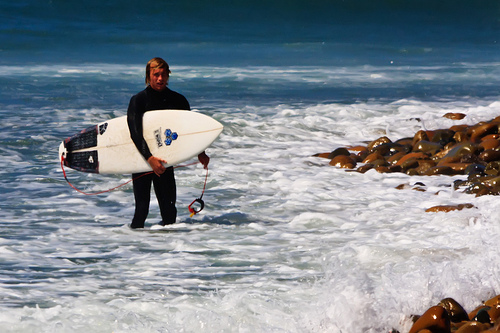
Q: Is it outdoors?
A: Yes, it is outdoors.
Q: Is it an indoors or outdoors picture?
A: It is outdoors.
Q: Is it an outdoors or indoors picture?
A: It is outdoors.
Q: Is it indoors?
A: No, it is outdoors.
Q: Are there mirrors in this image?
A: No, there are no mirrors.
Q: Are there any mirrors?
A: No, there are no mirrors.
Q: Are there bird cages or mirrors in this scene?
A: No, there are no mirrors or bird cages.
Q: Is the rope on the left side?
A: Yes, the rope is on the left of the image.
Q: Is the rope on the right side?
A: No, the rope is on the left of the image.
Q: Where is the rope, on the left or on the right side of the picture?
A: The rope is on the left of the image.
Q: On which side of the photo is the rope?
A: The rope is on the left of the image.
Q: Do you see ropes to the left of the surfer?
A: Yes, there is a rope to the left of the surfer.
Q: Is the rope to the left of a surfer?
A: Yes, the rope is to the left of a surfer.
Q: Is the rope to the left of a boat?
A: No, the rope is to the left of a surfer.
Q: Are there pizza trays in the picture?
A: No, there are no pizza trays.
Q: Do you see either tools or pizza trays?
A: No, there are no pizza trays or tools.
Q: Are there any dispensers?
A: No, there are no dispensers.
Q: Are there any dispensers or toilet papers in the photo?
A: No, there are no dispensers or toilet papers.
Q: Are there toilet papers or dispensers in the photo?
A: No, there are no dispensers or toilet papers.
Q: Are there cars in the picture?
A: No, there are no cars.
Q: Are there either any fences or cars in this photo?
A: No, there are no cars or fences.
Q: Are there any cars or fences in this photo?
A: No, there are no cars or fences.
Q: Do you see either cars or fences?
A: No, there are no cars or fences.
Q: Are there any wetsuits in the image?
A: Yes, there is a wetsuit.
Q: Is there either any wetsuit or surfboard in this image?
A: Yes, there is a wetsuit.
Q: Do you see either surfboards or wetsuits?
A: Yes, there is a wetsuit.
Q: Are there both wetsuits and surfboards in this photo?
A: Yes, there are both a wetsuit and a surfboard.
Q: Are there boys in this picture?
A: No, there are no boys.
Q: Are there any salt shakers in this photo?
A: No, there are no salt shakers.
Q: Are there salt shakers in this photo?
A: No, there are no salt shakers.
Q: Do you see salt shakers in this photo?
A: No, there are no salt shakers.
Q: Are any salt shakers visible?
A: No, there are no salt shakers.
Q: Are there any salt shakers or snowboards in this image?
A: No, there are no salt shakers or snowboards.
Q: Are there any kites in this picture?
A: No, there are no kites.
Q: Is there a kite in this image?
A: No, there are no kites.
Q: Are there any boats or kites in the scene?
A: No, there are no kites or boats.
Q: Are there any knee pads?
A: No, there are no knee pads.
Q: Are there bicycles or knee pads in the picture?
A: No, there are no knee pads or bicycles.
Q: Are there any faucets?
A: No, there are no faucets.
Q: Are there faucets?
A: No, there are no faucets.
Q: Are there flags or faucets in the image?
A: No, there are no faucets or flags.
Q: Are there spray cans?
A: No, there are no spray cans.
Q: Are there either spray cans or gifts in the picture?
A: No, there are no spray cans or gifts.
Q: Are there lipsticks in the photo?
A: No, there are no lipsticks.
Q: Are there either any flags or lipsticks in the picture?
A: No, there are no lipsticks or flags.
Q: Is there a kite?
A: No, there are no kites.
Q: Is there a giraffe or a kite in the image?
A: No, there are no kites or giraffes.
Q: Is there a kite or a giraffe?
A: No, there are no kites or giraffes.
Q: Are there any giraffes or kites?
A: No, there are no kites or giraffes.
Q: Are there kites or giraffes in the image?
A: No, there are no kites or giraffes.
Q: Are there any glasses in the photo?
A: No, there are no glasses.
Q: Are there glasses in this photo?
A: No, there are no glasses.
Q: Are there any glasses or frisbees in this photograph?
A: No, there are no glasses or frisbees.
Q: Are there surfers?
A: Yes, there is a surfer.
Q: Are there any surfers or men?
A: Yes, there is a surfer.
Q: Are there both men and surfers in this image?
A: Yes, there are both a surfer and a man.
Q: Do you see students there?
A: No, there are no students.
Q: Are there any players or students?
A: No, there are no students or players.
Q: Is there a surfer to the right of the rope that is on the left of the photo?
A: Yes, there is a surfer to the right of the rope.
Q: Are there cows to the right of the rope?
A: No, there is a surfer to the right of the rope.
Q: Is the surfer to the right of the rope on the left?
A: Yes, the surfer is to the right of the rope.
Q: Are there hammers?
A: No, there are no hammers.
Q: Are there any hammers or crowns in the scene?
A: No, there are no hammers or crowns.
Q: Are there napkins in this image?
A: No, there are no napkins.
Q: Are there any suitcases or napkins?
A: No, there are no napkins or suitcases.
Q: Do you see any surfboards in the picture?
A: Yes, there is a surfboard.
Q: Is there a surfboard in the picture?
A: Yes, there is a surfboard.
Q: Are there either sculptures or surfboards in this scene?
A: Yes, there is a surfboard.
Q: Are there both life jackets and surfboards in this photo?
A: No, there is a surfboard but no life jackets.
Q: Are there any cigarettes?
A: No, there are no cigarettes.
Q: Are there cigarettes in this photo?
A: No, there are no cigarettes.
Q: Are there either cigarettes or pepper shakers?
A: No, there are no cigarettes or pepper shakers.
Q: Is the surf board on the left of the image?
A: Yes, the surf board is on the left of the image.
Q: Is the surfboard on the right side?
A: No, the surfboard is on the left of the image.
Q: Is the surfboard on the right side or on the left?
A: The surfboard is on the left of the image.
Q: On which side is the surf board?
A: The surf board is on the left of the image.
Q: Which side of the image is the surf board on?
A: The surf board is on the left of the image.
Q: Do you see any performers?
A: No, there are no performers.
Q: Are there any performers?
A: No, there are no performers.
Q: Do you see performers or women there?
A: No, there are no performers or women.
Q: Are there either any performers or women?
A: No, there are no performers or women.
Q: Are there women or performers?
A: No, there are no performers or women.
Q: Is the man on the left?
A: Yes, the man is on the left of the image.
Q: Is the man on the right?
A: No, the man is on the left of the image.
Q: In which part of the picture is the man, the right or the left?
A: The man is on the left of the image.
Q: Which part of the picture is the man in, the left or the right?
A: The man is on the left of the image.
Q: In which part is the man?
A: The man is on the left of the image.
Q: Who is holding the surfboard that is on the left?
A: The man is holding the surf board.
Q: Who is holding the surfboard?
A: The man is holding the surf board.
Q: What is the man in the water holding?
A: The man is holding the surfboard.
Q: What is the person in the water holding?
A: The man is holding the surfboard.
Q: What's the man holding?
A: The man is holding the surfboard.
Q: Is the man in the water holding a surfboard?
A: Yes, the man is holding a surfboard.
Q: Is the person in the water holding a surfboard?
A: Yes, the man is holding a surfboard.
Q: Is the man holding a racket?
A: No, the man is holding a surfboard.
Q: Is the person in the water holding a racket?
A: No, the man is holding a surfboard.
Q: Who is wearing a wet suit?
A: The man is wearing a wet suit.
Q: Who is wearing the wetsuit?
A: The man is wearing a wet suit.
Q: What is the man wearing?
A: The man is wearing a wetsuit.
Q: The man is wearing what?
A: The man is wearing a wetsuit.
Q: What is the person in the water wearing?
A: The man is wearing a wetsuit.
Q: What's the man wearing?
A: The man is wearing a wetsuit.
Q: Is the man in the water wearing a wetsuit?
A: Yes, the man is wearing a wetsuit.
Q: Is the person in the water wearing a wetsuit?
A: Yes, the man is wearing a wetsuit.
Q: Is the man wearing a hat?
A: No, the man is wearing a wetsuit.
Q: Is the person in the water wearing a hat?
A: No, the man is wearing a wetsuit.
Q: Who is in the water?
A: The man is in the water.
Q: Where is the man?
A: The man is in the water.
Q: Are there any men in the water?
A: Yes, there is a man in the water.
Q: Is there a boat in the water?
A: No, there is a man in the water.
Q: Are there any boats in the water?
A: No, there is a man in the water.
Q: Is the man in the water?
A: Yes, the man is in the water.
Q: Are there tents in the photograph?
A: No, there are no tents.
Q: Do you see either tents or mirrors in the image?
A: No, there are no tents or mirrors.